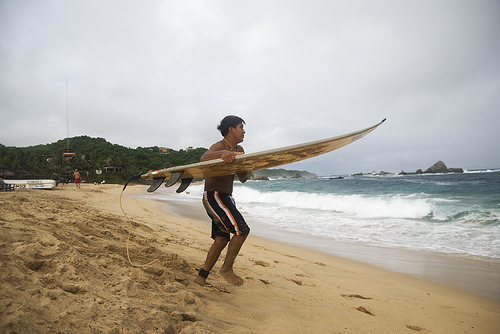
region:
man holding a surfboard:
[100, 70, 430, 248]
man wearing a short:
[150, 90, 275, 305]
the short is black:
[193, 192, 282, 239]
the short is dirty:
[193, 190, 254, 258]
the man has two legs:
[170, 207, 290, 308]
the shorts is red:
[65, 171, 90, 183]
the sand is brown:
[40, 210, 165, 291]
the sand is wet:
[365, 246, 435, 286]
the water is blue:
[342, 185, 457, 216]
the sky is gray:
[190, 29, 429, 152]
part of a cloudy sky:
[308, 19, 435, 77]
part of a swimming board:
[277, 130, 339, 177]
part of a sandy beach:
[289, 257, 361, 324]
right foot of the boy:
[222, 267, 247, 289]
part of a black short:
[201, 197, 234, 232]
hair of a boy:
[223, 115, 237, 125]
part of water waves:
[361, 177, 443, 234]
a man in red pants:
[68, 165, 84, 190]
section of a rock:
[426, 151, 456, 174]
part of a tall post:
[56, 92, 85, 161]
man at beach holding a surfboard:
[170, 110, 255, 290]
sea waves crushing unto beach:
[245, 180, 495, 240]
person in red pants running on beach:
[67, 166, 82, 192]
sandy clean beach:
[2, 181, 497, 328]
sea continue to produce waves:
[251, 172, 496, 262]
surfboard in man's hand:
[145, 115, 387, 196]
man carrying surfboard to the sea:
[194, 113, 259, 294]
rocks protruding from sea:
[353, 154, 472, 179]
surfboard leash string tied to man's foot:
[113, 169, 212, 280]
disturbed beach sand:
[5, 187, 195, 332]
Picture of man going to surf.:
[83, 34, 429, 315]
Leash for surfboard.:
[118, 167, 216, 288]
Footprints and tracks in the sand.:
[26, 193, 173, 324]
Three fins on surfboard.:
[143, 167, 195, 194]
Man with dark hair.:
[201, 110, 246, 203]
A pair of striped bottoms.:
[189, 180, 251, 241]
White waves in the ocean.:
[282, 174, 447, 247]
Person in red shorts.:
[70, 163, 85, 188]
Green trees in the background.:
[16, 134, 112, 174]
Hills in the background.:
[23, 139, 162, 183]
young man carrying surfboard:
[130, 106, 394, 290]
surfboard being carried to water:
[140, 116, 392, 179]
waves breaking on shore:
[239, 184, 497, 249]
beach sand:
[8, 190, 145, 331]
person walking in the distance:
[71, 166, 83, 187]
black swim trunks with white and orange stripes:
[201, 187, 251, 237]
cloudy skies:
[5, 3, 499, 113]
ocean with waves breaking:
[266, 172, 497, 247]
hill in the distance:
[403, 157, 467, 175]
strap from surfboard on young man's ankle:
[186, 256, 209, 281]